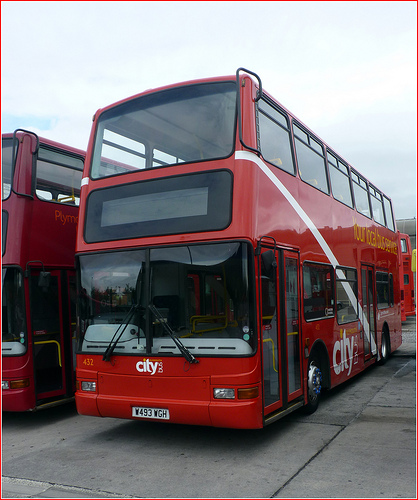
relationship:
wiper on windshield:
[102, 262, 143, 361] [82, 260, 136, 339]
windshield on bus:
[82, 260, 136, 339] [74, 67, 401, 429]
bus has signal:
[74, 67, 401, 429] [235, 378, 259, 403]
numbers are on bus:
[83, 358, 93, 365] [88, 95, 413, 409]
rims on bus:
[307, 359, 324, 400] [74, 67, 401, 429]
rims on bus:
[381, 336, 386, 355] [74, 67, 401, 429]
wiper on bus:
[148, 268, 199, 364] [74, 67, 401, 429]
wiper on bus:
[102, 262, 143, 361] [74, 67, 401, 429]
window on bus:
[97, 89, 221, 179] [74, 67, 401, 429]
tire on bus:
[284, 354, 340, 439] [75, 67, 384, 495]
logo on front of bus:
[111, 346, 179, 382] [74, 67, 401, 429]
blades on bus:
[100, 304, 138, 363] [74, 67, 401, 429]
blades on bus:
[146, 304, 197, 366] [74, 67, 401, 429]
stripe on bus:
[234, 147, 378, 356] [72, 66, 408, 320]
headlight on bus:
[214, 387, 236, 399] [74, 67, 401, 429]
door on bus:
[252, 239, 284, 419] [74, 67, 401, 429]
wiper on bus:
[144, 302, 200, 365] [84, 92, 402, 435]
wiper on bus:
[100, 293, 139, 359] [84, 92, 402, 435]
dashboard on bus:
[76, 317, 252, 354] [84, 92, 402, 435]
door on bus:
[252, 239, 284, 419] [56, 74, 401, 457]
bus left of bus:
[75, 71, 416, 397] [2, 125, 107, 436]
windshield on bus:
[92, 81, 235, 181] [74, 67, 401, 429]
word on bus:
[332, 329, 354, 376] [74, 67, 401, 429]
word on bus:
[332, 329, 354, 376] [0, 128, 85, 411]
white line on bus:
[231, 147, 382, 359] [74, 67, 401, 429]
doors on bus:
[20, 260, 82, 411] [0, 128, 146, 416]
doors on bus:
[356, 260, 379, 365] [395, 229, 414, 323]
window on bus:
[90, 81, 237, 180] [88, 109, 400, 420]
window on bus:
[252, 95, 287, 169] [52, 77, 400, 413]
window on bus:
[252, 95, 287, 169] [74, 67, 401, 429]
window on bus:
[293, 125, 328, 194] [74, 67, 401, 429]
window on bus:
[324, 147, 352, 204] [74, 67, 401, 429]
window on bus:
[352, 171, 371, 216] [74, 67, 401, 429]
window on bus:
[366, 183, 385, 226] [74, 67, 401, 429]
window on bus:
[334, 265, 358, 323] [74, 67, 401, 429]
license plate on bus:
[130, 402, 170, 421] [74, 67, 401, 429]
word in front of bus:
[134, 358, 159, 376] [74, 67, 401, 429]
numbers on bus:
[78, 355, 95, 366] [74, 67, 401, 429]